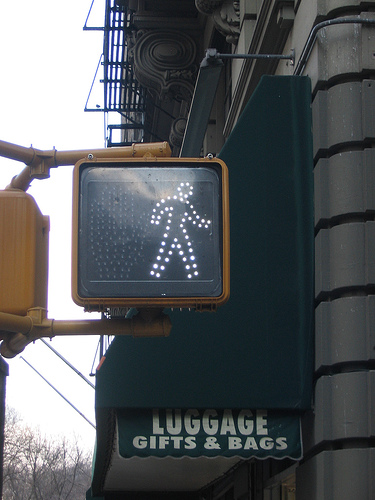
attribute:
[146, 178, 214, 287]
person — WHITE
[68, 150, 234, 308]
sign — dark yellow, Metal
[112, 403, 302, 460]
sign — green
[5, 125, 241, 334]
streetsign — pole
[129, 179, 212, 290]
man — walking character 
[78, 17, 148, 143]
escape — Black metal fire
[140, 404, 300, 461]
letters — White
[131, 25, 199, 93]
work — scroll, Cement 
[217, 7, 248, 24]
leaf — Cement 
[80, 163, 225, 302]
sign — shows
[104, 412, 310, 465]
sign — advertising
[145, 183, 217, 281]
bulbs —  white 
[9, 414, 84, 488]
leaves — no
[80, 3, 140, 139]
escape — fire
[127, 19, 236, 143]
sandstone — carved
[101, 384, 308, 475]
sign —  green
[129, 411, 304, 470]
letters —  white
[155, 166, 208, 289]
symbol — walk 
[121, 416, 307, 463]
sign — luggage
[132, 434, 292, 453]
sign — gifts & bags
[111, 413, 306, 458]
sign — GREEN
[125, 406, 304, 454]
letters — white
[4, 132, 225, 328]
sign — YELLOW, BLACK, WALK, DON'T WALK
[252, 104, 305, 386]
awning — DARK GREEN, BUSINESS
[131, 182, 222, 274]
signage — CROSSING, PEDESTRIAN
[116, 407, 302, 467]
signage — BAGS, GIFTS, LUGGAGE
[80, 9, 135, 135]
outdoor — EXIT, FIRE, STEEL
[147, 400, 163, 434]
letter — WHITE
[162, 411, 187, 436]
letter — white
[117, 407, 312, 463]
sign — green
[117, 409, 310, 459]
sign — green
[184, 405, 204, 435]
letter — white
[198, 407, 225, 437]
letter — white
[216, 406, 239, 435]
letter — white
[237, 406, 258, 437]
letter — white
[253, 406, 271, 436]
letter — white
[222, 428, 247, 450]
letter — white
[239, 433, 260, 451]
letter — white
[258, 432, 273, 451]
letter — white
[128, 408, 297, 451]
letters — white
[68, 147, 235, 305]
walk sign — yellow